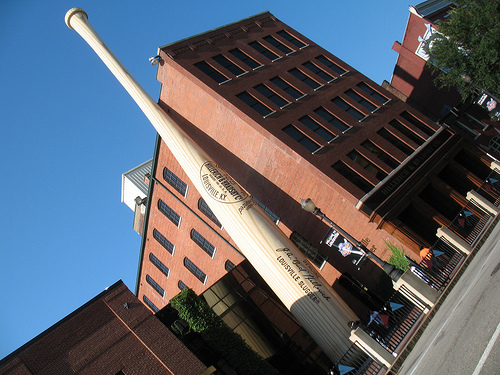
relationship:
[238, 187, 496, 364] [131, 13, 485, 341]
fence in front of building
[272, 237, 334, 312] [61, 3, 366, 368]
writing on bat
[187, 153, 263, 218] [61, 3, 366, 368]
label of bat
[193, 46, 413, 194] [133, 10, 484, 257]
windows on buildings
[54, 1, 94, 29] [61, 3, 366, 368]
knob of bat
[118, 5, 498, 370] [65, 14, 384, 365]
building honors ruth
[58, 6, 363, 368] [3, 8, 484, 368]
bat in world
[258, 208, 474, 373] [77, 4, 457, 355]
people at museum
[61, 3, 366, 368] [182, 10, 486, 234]
bat leaning building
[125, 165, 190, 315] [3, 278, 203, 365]
windows to building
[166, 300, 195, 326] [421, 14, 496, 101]
leaves to tree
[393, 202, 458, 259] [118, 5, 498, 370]
doorway to building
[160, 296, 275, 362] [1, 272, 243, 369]
vine growing building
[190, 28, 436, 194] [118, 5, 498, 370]
windows on building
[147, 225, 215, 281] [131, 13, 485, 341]
windows on building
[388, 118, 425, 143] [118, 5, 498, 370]
window on building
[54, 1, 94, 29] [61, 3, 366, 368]
knob on bat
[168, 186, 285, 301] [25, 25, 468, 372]
window on building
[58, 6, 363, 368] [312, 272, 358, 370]
bat casting shadow